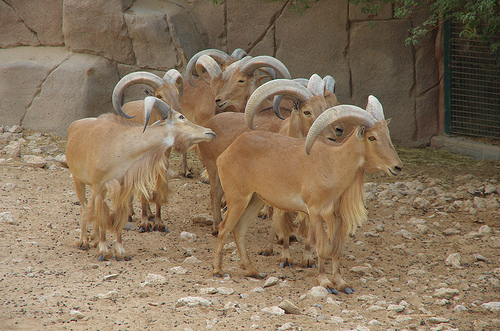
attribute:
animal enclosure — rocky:
[1, 0, 498, 331]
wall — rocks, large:
[2, 0, 442, 138]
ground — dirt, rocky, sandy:
[2, 139, 500, 330]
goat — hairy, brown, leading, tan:
[211, 95, 403, 299]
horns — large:
[304, 94, 384, 155]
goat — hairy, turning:
[66, 98, 217, 263]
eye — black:
[179, 113, 185, 121]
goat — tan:
[215, 55, 291, 108]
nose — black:
[395, 162, 404, 172]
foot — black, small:
[335, 279, 355, 294]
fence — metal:
[443, 0, 499, 149]